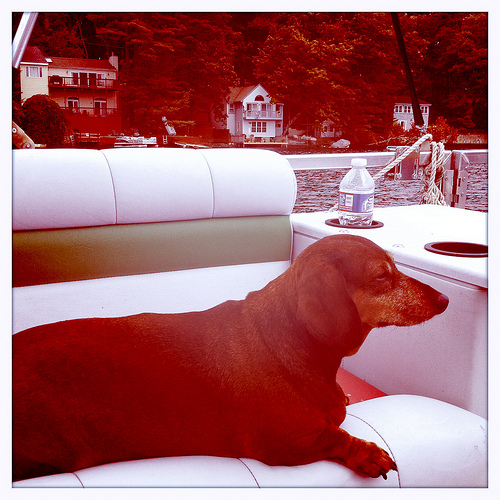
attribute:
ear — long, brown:
[296, 270, 360, 351]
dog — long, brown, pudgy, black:
[13, 234, 449, 479]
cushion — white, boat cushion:
[10, 392, 485, 487]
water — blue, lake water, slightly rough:
[295, 148, 404, 232]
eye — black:
[374, 267, 394, 278]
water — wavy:
[305, 171, 332, 208]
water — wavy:
[293, 156, 489, 211]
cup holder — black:
[421, 237, 488, 260]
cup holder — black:
[327, 214, 385, 228]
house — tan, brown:
[12, 0, 136, 115]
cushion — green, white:
[2, 214, 296, 281]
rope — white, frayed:
[310, 92, 452, 212]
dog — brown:
[3, 235, 416, 476]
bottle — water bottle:
[320, 161, 394, 223]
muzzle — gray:
[360, 274, 449, 328]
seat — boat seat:
[13, 144, 488, 489]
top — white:
[347, 156, 370, 170]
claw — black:
[373, 469, 389, 479]